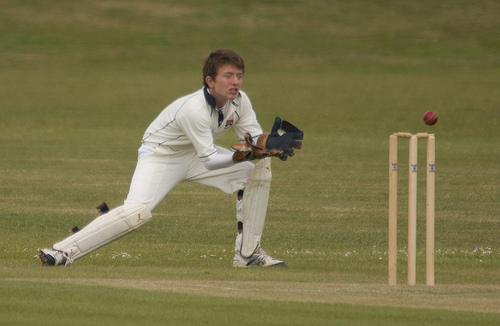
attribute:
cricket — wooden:
[386, 133, 437, 294]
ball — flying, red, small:
[424, 112, 438, 126]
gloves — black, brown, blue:
[232, 116, 305, 163]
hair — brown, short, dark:
[205, 51, 245, 90]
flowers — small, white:
[87, 246, 499, 265]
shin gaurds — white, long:
[53, 158, 273, 257]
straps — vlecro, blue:
[69, 190, 246, 237]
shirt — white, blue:
[142, 90, 262, 169]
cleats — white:
[40, 250, 285, 273]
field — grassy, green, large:
[2, 3, 499, 325]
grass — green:
[0, 1, 499, 324]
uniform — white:
[56, 89, 274, 249]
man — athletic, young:
[36, 44, 287, 278]